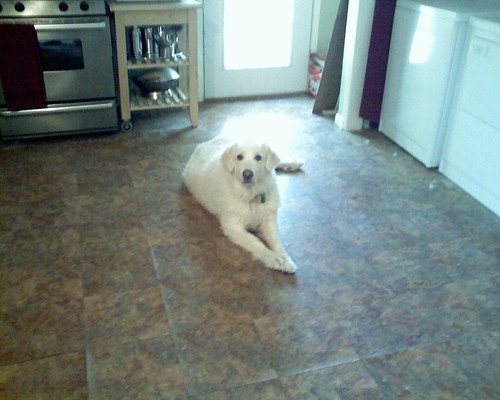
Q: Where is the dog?
A: In the kitchen.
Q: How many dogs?
A: One.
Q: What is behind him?
A: The door.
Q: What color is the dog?
A: White.